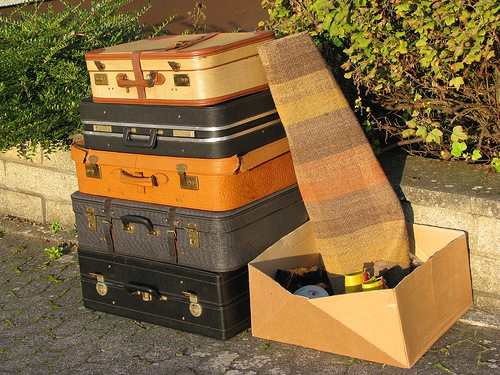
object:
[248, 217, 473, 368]
box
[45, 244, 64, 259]
weed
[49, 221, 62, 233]
weed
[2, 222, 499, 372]
road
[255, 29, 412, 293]
blanket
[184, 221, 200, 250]
lock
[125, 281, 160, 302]
handle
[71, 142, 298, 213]
suitcase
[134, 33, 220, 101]
strap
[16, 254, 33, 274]
crack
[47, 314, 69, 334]
crack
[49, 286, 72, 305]
crack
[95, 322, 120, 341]
crack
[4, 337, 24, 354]
crack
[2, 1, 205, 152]
bush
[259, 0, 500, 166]
bush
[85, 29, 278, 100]
suitcase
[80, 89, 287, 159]
suitcase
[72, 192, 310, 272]
suitcase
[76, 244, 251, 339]
suitcase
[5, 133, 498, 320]
retaining wall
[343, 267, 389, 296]
object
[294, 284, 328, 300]
object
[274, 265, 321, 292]
object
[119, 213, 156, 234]
handle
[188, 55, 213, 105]
light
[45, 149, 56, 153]
leaf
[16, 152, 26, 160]
leaf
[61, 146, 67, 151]
leaf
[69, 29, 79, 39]
leaf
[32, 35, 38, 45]
leaf